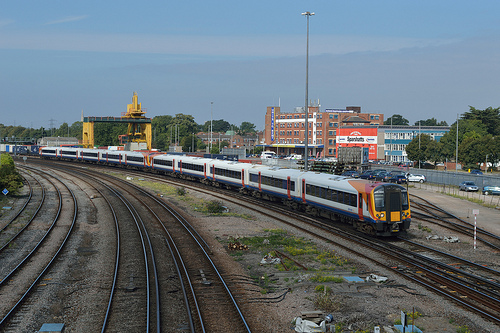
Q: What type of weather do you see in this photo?
A: It is clear.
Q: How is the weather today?
A: It is clear.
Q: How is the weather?
A: It is clear.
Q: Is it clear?
A: Yes, it is clear.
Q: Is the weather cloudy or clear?
A: It is clear.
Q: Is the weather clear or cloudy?
A: It is clear.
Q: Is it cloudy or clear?
A: It is clear.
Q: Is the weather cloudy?
A: No, it is clear.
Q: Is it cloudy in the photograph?
A: No, it is clear.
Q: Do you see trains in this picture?
A: Yes, there is a train.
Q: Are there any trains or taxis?
A: Yes, there is a train.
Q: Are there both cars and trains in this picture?
A: Yes, there are both a train and a car.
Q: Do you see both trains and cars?
A: Yes, there are both a train and a car.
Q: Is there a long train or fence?
A: Yes, there is a long train.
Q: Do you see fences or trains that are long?
A: Yes, the train is long.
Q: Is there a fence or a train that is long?
A: Yes, the train is long.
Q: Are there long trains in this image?
A: Yes, there is a long train.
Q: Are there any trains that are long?
A: Yes, there is a train that is long.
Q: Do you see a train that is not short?
A: Yes, there is a long train.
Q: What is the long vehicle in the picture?
A: The vehicle is a train.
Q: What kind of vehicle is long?
A: The vehicle is a train.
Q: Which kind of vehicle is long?
A: The vehicle is a train.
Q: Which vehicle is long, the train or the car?
A: The train is long.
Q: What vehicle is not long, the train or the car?
A: The car is not long.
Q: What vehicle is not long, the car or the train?
A: The car is not long.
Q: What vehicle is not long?
A: The vehicle is a car.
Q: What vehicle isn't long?
A: The vehicle is a car.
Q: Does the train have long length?
A: Yes, the train is long.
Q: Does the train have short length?
A: No, the train is long.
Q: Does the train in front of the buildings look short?
A: No, the train is long.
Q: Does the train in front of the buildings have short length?
A: No, the train is long.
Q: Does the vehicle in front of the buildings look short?
A: No, the train is long.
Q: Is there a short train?
A: No, there is a train but it is long.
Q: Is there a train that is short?
A: No, there is a train but it is long.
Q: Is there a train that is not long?
A: No, there is a train but it is long.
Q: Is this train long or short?
A: The train is long.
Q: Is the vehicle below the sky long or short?
A: The train is long.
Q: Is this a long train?
A: Yes, this is a long train.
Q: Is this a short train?
A: No, this is a long train.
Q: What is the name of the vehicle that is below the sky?
A: The vehicle is a train.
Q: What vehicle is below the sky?
A: The vehicle is a train.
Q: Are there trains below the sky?
A: Yes, there is a train below the sky.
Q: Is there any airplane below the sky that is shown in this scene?
A: No, there is a train below the sky.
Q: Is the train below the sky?
A: Yes, the train is below the sky.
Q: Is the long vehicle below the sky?
A: Yes, the train is below the sky.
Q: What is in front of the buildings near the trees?
A: The train is in front of the buildings.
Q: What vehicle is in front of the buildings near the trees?
A: The vehicle is a train.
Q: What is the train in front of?
A: The train is in front of the buildings.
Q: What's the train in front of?
A: The train is in front of the buildings.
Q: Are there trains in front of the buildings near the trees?
A: Yes, there is a train in front of the buildings.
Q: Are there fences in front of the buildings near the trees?
A: No, there is a train in front of the buildings.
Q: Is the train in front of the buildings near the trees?
A: Yes, the train is in front of the buildings.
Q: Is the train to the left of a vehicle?
A: Yes, the train is to the left of a vehicle.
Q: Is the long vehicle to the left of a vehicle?
A: Yes, the train is to the left of a vehicle.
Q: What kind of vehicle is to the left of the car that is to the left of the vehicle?
A: The vehicle is a train.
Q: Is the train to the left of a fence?
A: No, the train is to the left of the car.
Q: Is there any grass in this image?
A: Yes, there is grass.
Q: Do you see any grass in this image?
A: Yes, there is grass.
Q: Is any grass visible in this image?
A: Yes, there is grass.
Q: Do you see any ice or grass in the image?
A: Yes, there is grass.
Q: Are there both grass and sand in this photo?
A: No, there is grass but no sand.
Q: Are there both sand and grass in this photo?
A: No, there is grass but no sand.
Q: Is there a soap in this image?
A: No, there are no soaps.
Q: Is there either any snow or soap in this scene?
A: No, there are no soaps or snow.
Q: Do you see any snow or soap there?
A: No, there are no soaps or snow.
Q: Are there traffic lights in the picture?
A: No, there are no traffic lights.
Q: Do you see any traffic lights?
A: No, there are no traffic lights.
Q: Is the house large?
A: Yes, the house is large.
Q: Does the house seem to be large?
A: Yes, the house is large.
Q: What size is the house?
A: The house is large.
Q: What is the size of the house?
A: The house is large.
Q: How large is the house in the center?
A: The house is large.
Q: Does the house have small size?
A: No, the house is large.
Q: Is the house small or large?
A: The house is large.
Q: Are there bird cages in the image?
A: No, there are no bird cages.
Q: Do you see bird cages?
A: No, there are no bird cages.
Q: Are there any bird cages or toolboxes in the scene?
A: No, there are no bird cages or toolboxes.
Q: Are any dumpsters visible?
A: No, there are no dumpsters.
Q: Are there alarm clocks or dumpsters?
A: No, there are no dumpsters or alarm clocks.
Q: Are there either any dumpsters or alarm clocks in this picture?
A: No, there are no dumpsters or alarm clocks.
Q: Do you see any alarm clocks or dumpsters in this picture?
A: No, there are no dumpsters or alarm clocks.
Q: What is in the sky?
A: The clouds are in the sky.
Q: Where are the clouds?
A: The clouds are in the sky.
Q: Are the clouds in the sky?
A: Yes, the clouds are in the sky.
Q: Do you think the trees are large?
A: Yes, the trees are large.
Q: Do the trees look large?
A: Yes, the trees are large.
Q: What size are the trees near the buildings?
A: The trees are large.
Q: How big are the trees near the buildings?
A: The trees are large.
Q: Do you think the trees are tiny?
A: No, the trees are large.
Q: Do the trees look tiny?
A: No, the trees are large.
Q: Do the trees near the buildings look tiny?
A: No, the trees are large.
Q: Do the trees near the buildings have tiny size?
A: No, the trees are large.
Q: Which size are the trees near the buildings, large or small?
A: The trees are large.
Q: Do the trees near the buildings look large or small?
A: The trees are large.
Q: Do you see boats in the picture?
A: No, there are no boats.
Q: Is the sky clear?
A: Yes, the sky is clear.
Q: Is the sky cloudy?
A: No, the sky is clear.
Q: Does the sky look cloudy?
A: No, the sky is clear.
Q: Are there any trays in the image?
A: No, there are no trays.